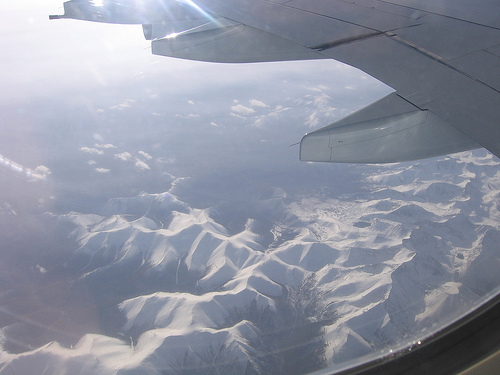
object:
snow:
[0, 0, 500, 375]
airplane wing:
[47, 0, 500, 164]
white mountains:
[2, 67, 499, 364]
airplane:
[46, 0, 500, 375]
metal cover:
[297, 91, 485, 162]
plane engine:
[301, 85, 489, 163]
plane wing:
[296, 90, 484, 166]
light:
[87, 1, 226, 33]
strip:
[307, 287, 500, 375]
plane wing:
[148, 17, 330, 64]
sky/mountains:
[18, 40, 128, 177]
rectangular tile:
[316, 33, 449, 107]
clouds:
[81, 141, 151, 173]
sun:
[94, 0, 211, 24]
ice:
[141, 290, 196, 318]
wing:
[154, 14, 338, 65]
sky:
[1, 0, 135, 82]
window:
[3, 0, 499, 375]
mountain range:
[3, 85, 500, 373]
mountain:
[1, 64, 499, 373]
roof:
[47, 0, 500, 167]